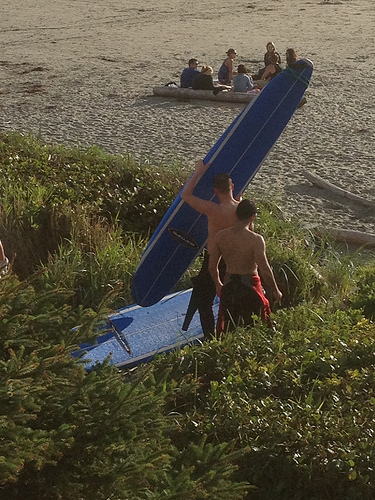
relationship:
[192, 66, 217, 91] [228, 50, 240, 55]
woman with sunglasses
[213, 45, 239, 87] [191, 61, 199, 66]
woman with sunglasses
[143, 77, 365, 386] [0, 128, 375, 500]
surfboard in grass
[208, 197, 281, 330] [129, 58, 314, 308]
man holding board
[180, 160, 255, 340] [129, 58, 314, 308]
man holding board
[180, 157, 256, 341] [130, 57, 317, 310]
man holding surfboard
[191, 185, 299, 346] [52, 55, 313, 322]
man holding surfboard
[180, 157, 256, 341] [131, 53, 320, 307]
man holding blue surfboard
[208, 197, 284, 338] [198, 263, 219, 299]
man in suits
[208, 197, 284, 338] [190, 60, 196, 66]
man with sunglasses